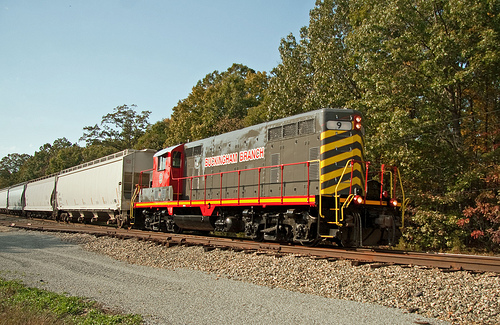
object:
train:
[1, 108, 410, 248]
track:
[1, 213, 499, 274]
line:
[339, 198, 402, 207]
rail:
[343, 249, 499, 271]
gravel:
[90, 236, 499, 323]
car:
[56, 148, 158, 212]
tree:
[170, 63, 262, 149]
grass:
[1, 278, 145, 324]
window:
[156, 152, 169, 172]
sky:
[0, 2, 210, 66]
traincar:
[22, 171, 57, 218]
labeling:
[204, 147, 264, 168]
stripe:
[320, 129, 358, 154]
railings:
[333, 158, 405, 206]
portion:
[151, 143, 184, 200]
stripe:
[133, 197, 316, 207]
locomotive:
[129, 108, 405, 249]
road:
[0, 229, 453, 324]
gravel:
[388, 273, 442, 300]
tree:
[367, 0, 499, 170]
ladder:
[120, 153, 135, 216]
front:
[318, 106, 406, 248]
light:
[355, 123, 363, 131]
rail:
[170, 160, 319, 181]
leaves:
[459, 174, 499, 244]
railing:
[327, 159, 354, 226]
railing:
[170, 160, 312, 205]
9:
[336, 120, 342, 129]